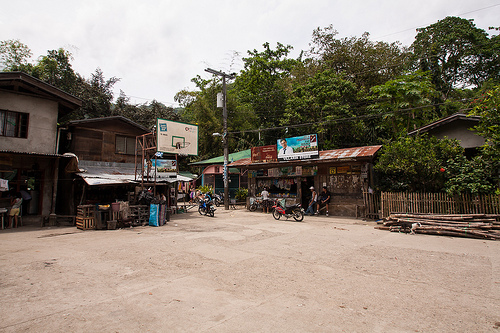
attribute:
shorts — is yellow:
[9, 204, 21, 218]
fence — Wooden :
[376, 188, 498, 235]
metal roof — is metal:
[335, 140, 360, 156]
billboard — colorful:
[277, 135, 316, 157]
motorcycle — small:
[189, 191, 227, 215]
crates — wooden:
[67, 195, 107, 227]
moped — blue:
[193, 190, 218, 221]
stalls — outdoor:
[2, 76, 497, 247]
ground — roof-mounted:
[368, 65, 392, 105]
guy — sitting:
[313, 184, 331, 219]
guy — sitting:
[305, 183, 319, 218]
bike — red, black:
[195, 194, 215, 218]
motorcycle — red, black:
[270, 194, 305, 220]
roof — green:
[297, 117, 387, 159]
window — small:
[0, 109, 28, 138]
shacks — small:
[230, 155, 357, 225]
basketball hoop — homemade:
[172, 137, 192, 154]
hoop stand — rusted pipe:
[132, 135, 159, 225]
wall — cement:
[333, 173, 357, 198]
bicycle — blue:
[198, 201, 216, 214]